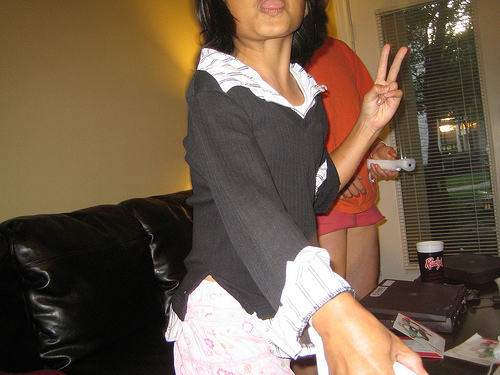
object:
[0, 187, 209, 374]
couch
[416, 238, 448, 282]
coffee cup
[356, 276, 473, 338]
briefcase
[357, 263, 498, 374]
table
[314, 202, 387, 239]
pants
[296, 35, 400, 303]
female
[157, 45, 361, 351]
sweater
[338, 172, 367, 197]
hands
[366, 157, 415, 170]
control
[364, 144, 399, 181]
hand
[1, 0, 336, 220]
wall